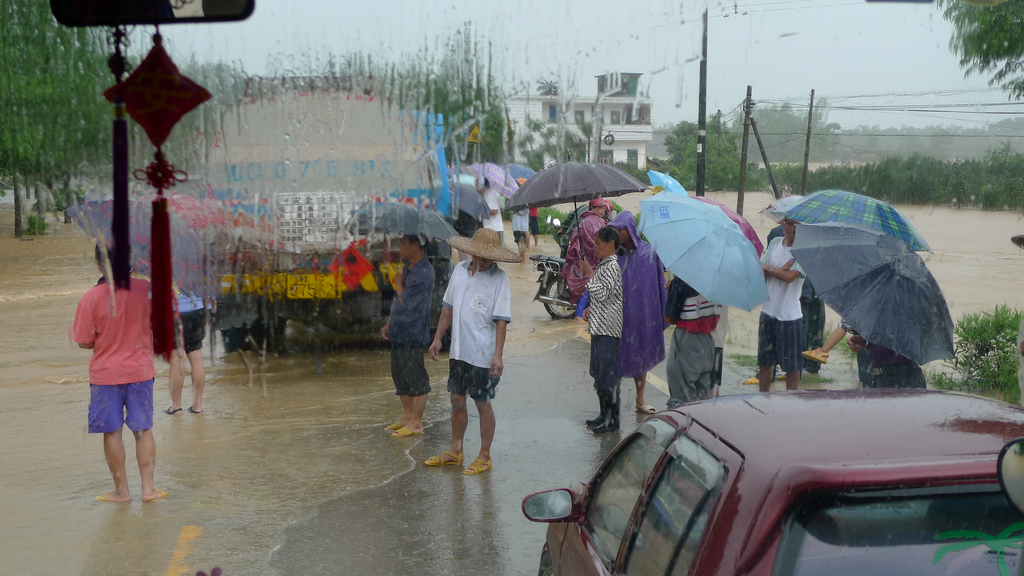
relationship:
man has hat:
[424, 226, 511, 480] [445, 225, 526, 264]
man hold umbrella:
[424, 228, 523, 475] [346, 196, 462, 247]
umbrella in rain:
[765, 185, 934, 255] [3, 2, 1023, 574]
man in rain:
[424, 228, 523, 475] [3, 2, 1023, 574]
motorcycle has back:
[529, 252, 586, 321] [532, 252, 569, 268]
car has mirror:
[521, 386, 1023, 573] [520, 487, 577, 524]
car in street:
[521, 386, 1023, 573] [165, 326, 770, 573]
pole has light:
[730, 84, 756, 218] [740, 98, 758, 128]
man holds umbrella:
[376, 230, 432, 438] [346, 196, 462, 247]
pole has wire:
[730, 84, 756, 218] [746, 98, 1022, 113]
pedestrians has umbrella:
[580, 227, 624, 434] [505, 156, 652, 276]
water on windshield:
[769, 479, 1023, 572] [759, 470, 1022, 574]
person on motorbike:
[562, 196, 619, 329] [529, 252, 586, 321]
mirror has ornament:
[47, 0, 255, 30] [105, 27, 214, 359]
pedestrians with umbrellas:
[579, 215, 807, 431] [506, 161, 811, 322]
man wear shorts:
[424, 228, 523, 475] [384, 343, 500, 404]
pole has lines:
[730, 84, 756, 218] [745, 95, 1022, 143]